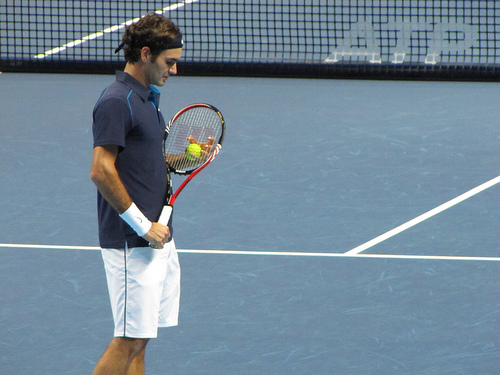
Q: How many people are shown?
A: One.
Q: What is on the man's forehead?
A: A headband.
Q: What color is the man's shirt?
A: Blue.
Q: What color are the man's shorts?
A: White.